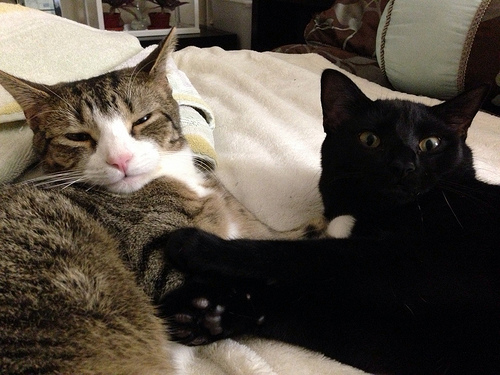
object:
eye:
[416, 135, 445, 152]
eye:
[357, 128, 380, 148]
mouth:
[98, 168, 155, 187]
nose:
[106, 152, 132, 172]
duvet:
[0, 0, 500, 375]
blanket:
[0, 0, 218, 185]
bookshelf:
[20, 0, 200, 38]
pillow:
[0, 3, 143, 116]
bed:
[0, 4, 495, 375]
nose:
[391, 158, 416, 175]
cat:
[0, 27, 230, 375]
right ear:
[138, 26, 178, 75]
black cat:
[136, 67, 499, 374]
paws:
[169, 298, 225, 347]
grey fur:
[56, 232, 73, 243]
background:
[0, 1, 305, 47]